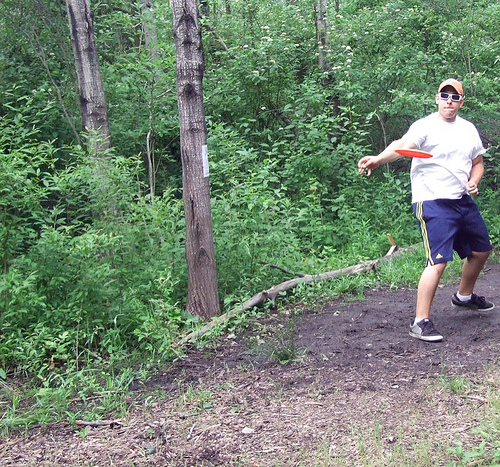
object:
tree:
[57, 0, 131, 318]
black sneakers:
[447, 291, 494, 314]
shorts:
[409, 192, 494, 270]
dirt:
[0, 251, 499, 466]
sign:
[200, 141, 209, 181]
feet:
[448, 290, 495, 314]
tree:
[165, 0, 223, 325]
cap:
[433, 77, 465, 97]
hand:
[353, 154, 380, 179]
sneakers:
[404, 316, 442, 340]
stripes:
[416, 196, 434, 266]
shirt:
[398, 107, 487, 206]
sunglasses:
[434, 90, 466, 103]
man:
[355, 76, 495, 343]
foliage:
[264, 131, 276, 145]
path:
[0, 250, 499, 466]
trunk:
[167, 0, 221, 323]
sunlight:
[0, 363, 499, 464]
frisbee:
[391, 147, 437, 163]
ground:
[0, 265, 499, 466]